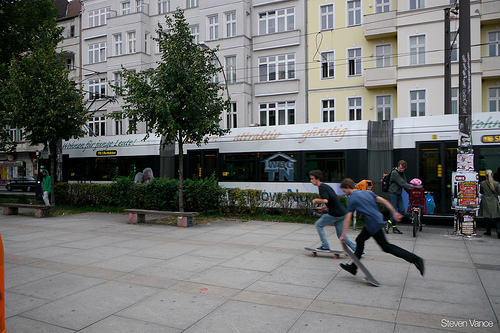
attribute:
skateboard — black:
[336, 238, 380, 291]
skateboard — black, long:
[302, 239, 354, 264]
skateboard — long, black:
[335, 232, 376, 288]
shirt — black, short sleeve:
[310, 184, 342, 213]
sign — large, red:
[452, 174, 481, 206]